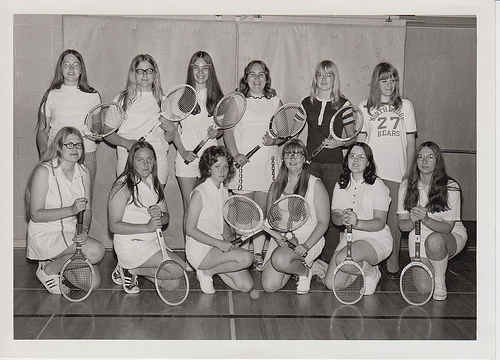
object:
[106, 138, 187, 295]
girl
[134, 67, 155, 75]
glasses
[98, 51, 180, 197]
girl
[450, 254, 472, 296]
ground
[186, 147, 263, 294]
girl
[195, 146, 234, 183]
hair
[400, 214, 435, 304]
racket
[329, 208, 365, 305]
racket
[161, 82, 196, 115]
racket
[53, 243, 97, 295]
racket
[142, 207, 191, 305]
racket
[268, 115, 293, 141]
black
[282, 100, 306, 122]
white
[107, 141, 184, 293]
female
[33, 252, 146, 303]
shoes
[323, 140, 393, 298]
girl w/shoes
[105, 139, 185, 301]
girl w/shoes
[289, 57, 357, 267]
girl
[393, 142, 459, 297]
girl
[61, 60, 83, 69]
glasses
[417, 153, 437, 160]
glasses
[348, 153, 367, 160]
glasses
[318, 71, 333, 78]
glasses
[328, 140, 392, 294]
girl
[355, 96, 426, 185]
jersey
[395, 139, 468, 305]
female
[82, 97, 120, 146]
racket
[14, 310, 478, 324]
stripe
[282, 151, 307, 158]
glasses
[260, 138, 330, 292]
girl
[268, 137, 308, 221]
pigtails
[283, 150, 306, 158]
glasses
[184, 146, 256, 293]
female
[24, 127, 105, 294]
girl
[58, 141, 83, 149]
glasses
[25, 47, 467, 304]
tennis team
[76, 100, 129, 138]
racket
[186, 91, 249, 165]
racket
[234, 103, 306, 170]
racket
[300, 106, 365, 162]
racket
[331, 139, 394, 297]
female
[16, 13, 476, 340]
photo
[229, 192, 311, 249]
racket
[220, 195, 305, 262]
racket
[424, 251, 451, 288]
socks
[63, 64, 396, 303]
team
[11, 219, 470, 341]
floor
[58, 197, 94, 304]
racket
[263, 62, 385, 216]
shirt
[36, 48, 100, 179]
girl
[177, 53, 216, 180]
girl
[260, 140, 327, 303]
girl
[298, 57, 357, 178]
girl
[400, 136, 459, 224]
hair